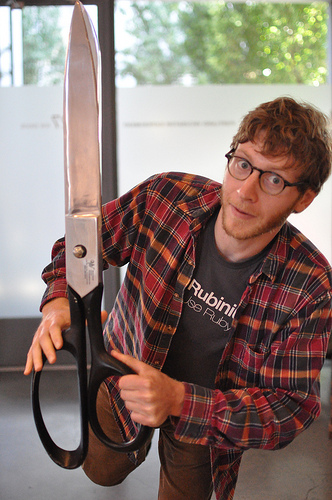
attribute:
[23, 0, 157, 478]
scissors — jumbo size, monumental, over-sized, oversized, gargantuan, herculean, brobdingnagian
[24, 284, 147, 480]
handle — black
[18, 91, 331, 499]
dude — huppster, young, mid-twenties, caucasian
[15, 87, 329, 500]
huppster — hipster=yuppie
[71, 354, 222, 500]
pants — brown, wrinkly, well-fitting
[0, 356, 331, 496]
floor — grey, concrete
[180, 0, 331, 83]
tree — of course, green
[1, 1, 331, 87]
window — clear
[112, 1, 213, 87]
tree — blurry blue green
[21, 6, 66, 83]
tree — blurry blue green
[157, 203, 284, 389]
shirt — t-shirt, black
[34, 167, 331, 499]
shirt — button down, grunge type, pendleton [approx], plaid, cotton, not flannel, orange, red, brown, grey, black, stiffer than flannel, something, open over t-shirt, too stiff 4 flannel, stiffish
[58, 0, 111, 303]
blades — grey, silvertone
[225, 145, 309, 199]
glasses — black, huppster, eyeglasses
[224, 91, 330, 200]
hair — red, slightly scruffy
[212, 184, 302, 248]
beard — red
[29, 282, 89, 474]
handle — curved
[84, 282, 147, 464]
handle — circular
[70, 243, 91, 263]
screw — hex cap type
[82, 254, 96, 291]
writing — unintelligible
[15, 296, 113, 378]
hand — large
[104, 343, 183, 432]
hand — large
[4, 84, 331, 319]
wall — white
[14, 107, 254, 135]
writing — indistinct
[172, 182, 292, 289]
collar — turn down type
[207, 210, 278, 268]
collar — matching ringer type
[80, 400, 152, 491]
knee — maybe kneeling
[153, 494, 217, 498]
knee — unpictured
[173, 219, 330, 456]
sleeve — long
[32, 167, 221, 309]
sleeve — long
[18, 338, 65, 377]
fingernails — unpolished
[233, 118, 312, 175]
bangs — messy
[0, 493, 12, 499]
'turkerworkers — imaginationless